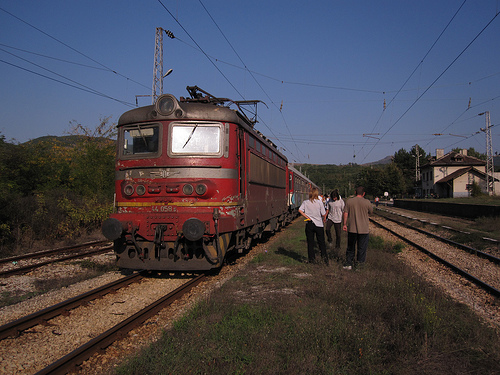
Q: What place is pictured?
A: It is a field.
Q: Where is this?
A: This is at the field.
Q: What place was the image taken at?
A: It was taken at the field.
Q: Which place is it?
A: It is a field.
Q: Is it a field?
A: Yes, it is a field.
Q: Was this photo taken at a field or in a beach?
A: It was taken at a field.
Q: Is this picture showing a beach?
A: No, the picture is showing a field.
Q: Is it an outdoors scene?
A: Yes, it is outdoors.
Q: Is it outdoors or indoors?
A: It is outdoors.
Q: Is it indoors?
A: No, it is outdoors.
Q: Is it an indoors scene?
A: No, it is outdoors.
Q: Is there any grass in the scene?
A: Yes, there is grass.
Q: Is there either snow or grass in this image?
A: Yes, there is grass.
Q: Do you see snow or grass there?
A: Yes, there is grass.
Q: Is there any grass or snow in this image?
A: Yes, there is grass.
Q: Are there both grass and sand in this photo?
A: No, there is grass but no sand.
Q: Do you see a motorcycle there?
A: No, there are no motorcycles.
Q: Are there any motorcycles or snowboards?
A: No, there are no motorcycles or snowboards.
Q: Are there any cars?
A: No, there are no cars.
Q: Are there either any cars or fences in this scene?
A: No, there are no cars or fences.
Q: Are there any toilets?
A: No, there are no toilets.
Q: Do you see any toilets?
A: No, there are no toilets.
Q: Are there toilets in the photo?
A: No, there are no toilets.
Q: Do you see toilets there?
A: No, there are no toilets.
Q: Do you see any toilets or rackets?
A: No, there are no toilets or rackets.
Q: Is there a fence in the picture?
A: No, there are no fences.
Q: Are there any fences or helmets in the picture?
A: No, there are no fences or helmets.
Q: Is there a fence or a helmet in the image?
A: No, there are no fences or helmets.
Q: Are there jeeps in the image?
A: No, there are no jeeps.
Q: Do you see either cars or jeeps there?
A: No, there are no jeeps or cars.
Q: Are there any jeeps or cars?
A: No, there are no jeeps or cars.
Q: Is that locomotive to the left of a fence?
A: No, the locomotive is to the left of a person.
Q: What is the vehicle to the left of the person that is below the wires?
A: The vehicle is a locomotive.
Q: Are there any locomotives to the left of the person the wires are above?
A: Yes, there is a locomotive to the left of the person.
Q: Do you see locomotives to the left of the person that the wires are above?
A: Yes, there is a locomotive to the left of the person.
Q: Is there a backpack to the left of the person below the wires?
A: No, there is a locomotive to the left of the person.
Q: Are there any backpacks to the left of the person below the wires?
A: No, there is a locomotive to the left of the person.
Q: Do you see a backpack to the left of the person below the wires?
A: No, there is a locomotive to the left of the person.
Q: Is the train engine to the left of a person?
A: Yes, the train engine is to the left of a person.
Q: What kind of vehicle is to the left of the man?
A: The vehicle is a locomotive.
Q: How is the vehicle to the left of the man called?
A: The vehicle is a locomotive.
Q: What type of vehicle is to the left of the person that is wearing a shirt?
A: The vehicle is a locomotive.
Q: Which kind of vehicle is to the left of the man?
A: The vehicle is a locomotive.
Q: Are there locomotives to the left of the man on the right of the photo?
A: Yes, there is a locomotive to the left of the man.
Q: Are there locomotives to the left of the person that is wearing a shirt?
A: Yes, there is a locomotive to the left of the man.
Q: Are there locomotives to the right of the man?
A: No, the locomotive is to the left of the man.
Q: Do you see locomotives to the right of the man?
A: No, the locomotive is to the left of the man.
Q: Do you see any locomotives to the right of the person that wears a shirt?
A: No, the locomotive is to the left of the man.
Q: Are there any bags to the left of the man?
A: No, there is a locomotive to the left of the man.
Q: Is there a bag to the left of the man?
A: No, there is a locomotive to the left of the man.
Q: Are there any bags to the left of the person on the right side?
A: No, there is a locomotive to the left of the man.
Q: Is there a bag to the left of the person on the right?
A: No, there is a locomotive to the left of the man.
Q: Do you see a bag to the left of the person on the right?
A: No, there is a locomotive to the left of the man.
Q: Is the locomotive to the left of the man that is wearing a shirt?
A: Yes, the locomotive is to the left of the man.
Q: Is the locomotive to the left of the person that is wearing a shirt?
A: Yes, the locomotive is to the left of the man.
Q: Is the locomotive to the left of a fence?
A: No, the locomotive is to the left of the man.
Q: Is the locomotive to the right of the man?
A: No, the locomotive is to the left of the man.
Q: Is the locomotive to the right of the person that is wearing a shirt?
A: No, the locomotive is to the left of the man.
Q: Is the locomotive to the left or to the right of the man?
A: The locomotive is to the left of the man.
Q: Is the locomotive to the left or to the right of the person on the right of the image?
A: The locomotive is to the left of the man.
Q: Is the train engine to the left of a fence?
A: No, the train engine is to the left of a person.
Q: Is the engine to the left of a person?
A: Yes, the engine is to the left of a person.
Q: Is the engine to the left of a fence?
A: No, the engine is to the left of a person.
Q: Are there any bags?
A: No, there are no bags.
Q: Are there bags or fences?
A: No, there are no bags or fences.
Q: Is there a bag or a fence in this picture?
A: No, there are no bags or fences.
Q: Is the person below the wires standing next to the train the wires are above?
A: Yes, the person is standing next to the train.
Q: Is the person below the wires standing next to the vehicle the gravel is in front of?
A: Yes, the person is standing next to the train.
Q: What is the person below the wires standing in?
A: The person is standing in the grass.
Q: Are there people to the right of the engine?
A: Yes, there is a person to the right of the engine.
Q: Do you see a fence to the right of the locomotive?
A: No, there is a person to the right of the locomotive.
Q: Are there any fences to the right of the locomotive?
A: No, there is a person to the right of the locomotive.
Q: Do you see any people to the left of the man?
A: Yes, there is a person to the left of the man.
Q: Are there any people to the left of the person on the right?
A: Yes, there is a person to the left of the man.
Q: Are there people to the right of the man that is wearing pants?
A: No, the person is to the left of the man.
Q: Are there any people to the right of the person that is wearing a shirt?
A: No, the person is to the left of the man.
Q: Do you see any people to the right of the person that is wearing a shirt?
A: No, the person is to the left of the man.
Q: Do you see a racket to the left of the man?
A: No, there is a person to the left of the man.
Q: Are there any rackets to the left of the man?
A: No, there is a person to the left of the man.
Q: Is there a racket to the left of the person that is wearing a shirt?
A: No, there is a person to the left of the man.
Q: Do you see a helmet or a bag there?
A: No, there are no helmets or bags.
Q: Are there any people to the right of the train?
A: Yes, there is a person to the right of the train.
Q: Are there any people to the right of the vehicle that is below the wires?
A: Yes, there is a person to the right of the train.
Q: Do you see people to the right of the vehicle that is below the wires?
A: Yes, there is a person to the right of the train.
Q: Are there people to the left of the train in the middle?
A: No, the person is to the right of the train.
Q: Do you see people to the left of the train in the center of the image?
A: No, the person is to the right of the train.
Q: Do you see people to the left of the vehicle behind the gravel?
A: No, the person is to the right of the train.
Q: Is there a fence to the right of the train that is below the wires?
A: No, there is a person to the right of the train.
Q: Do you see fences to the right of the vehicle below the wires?
A: No, there is a person to the right of the train.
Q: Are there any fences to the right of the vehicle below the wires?
A: No, there is a person to the right of the train.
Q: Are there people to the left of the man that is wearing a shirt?
A: Yes, there is a person to the left of the man.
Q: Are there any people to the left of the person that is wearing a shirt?
A: Yes, there is a person to the left of the man.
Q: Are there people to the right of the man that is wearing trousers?
A: No, the person is to the left of the man.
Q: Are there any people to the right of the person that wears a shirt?
A: No, the person is to the left of the man.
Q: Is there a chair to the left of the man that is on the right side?
A: No, there is a person to the left of the man.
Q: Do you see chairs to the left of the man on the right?
A: No, there is a person to the left of the man.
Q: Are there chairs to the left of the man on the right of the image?
A: No, there is a person to the left of the man.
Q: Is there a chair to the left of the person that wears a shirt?
A: No, there is a person to the left of the man.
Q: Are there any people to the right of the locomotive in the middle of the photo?
A: Yes, there is a person to the right of the locomotive.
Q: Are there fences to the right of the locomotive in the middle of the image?
A: No, there is a person to the right of the train engine.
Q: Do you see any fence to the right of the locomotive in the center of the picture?
A: No, there is a person to the right of the train engine.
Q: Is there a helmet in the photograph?
A: No, there are no helmets.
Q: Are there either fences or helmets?
A: No, there are no helmets or fences.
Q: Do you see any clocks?
A: No, there are no clocks.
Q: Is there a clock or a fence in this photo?
A: No, there are no clocks or fences.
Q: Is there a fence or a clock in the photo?
A: No, there are no clocks or fences.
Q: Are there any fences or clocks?
A: No, there are no clocks or fences.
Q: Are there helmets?
A: No, there are no helmets.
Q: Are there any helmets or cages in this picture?
A: No, there are no helmets or cages.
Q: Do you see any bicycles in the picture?
A: No, there are no bicycles.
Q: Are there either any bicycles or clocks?
A: No, there are no bicycles or clocks.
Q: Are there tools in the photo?
A: No, there are no tools.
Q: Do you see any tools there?
A: No, there are no tools.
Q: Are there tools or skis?
A: No, there are no tools or skis.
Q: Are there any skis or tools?
A: No, there are no tools or skis.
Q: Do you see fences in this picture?
A: No, there are no fences.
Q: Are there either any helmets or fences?
A: No, there are no fences or helmets.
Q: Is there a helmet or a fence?
A: No, there are no fences or helmets.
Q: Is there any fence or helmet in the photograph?
A: No, there are no fences or helmets.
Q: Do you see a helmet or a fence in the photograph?
A: No, there are no fences or helmets.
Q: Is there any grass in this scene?
A: Yes, there is grass.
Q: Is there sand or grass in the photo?
A: Yes, there is grass.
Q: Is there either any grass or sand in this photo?
A: Yes, there is grass.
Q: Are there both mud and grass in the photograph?
A: No, there is grass but no mud.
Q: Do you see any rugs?
A: No, there are no rugs.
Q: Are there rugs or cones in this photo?
A: No, there are no rugs or cones.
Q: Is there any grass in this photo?
A: Yes, there is grass.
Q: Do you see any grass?
A: Yes, there is grass.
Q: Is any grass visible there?
A: Yes, there is grass.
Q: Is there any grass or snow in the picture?
A: Yes, there is grass.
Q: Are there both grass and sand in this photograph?
A: No, there is grass but no sand.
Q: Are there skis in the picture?
A: No, there are no skis.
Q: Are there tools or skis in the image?
A: No, there are no skis or tools.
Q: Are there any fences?
A: No, there are no fences.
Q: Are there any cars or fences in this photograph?
A: No, there are no fences or cars.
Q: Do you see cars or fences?
A: No, there are no fences or cars.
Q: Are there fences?
A: No, there are no fences.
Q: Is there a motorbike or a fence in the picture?
A: No, there are no fences or motorcycles.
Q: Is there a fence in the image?
A: No, there are no fences.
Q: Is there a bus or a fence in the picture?
A: No, there are no fences or buses.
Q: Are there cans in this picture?
A: No, there are no cans.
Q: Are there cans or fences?
A: No, there are no cans or fences.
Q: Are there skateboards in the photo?
A: No, there are no skateboards.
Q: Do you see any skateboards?
A: No, there are no skateboards.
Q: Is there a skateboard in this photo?
A: No, there are no skateboards.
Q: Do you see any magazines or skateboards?
A: No, there are no skateboards or magazines.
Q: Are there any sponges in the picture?
A: No, there are no sponges.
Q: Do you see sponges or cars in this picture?
A: No, there are no sponges or cars.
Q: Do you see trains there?
A: Yes, there is a train.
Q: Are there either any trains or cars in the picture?
A: Yes, there is a train.